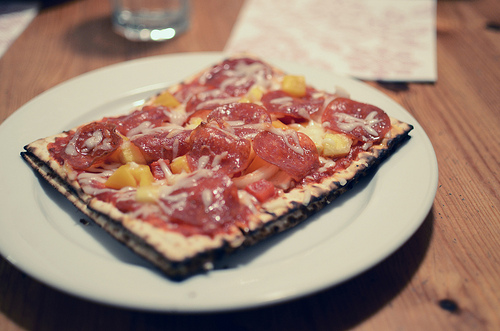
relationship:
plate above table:
[0, 54, 436, 314] [0, 6, 499, 328]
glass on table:
[106, 0, 193, 44] [0, 6, 499, 328]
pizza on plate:
[31, 62, 421, 265] [0, 54, 436, 314]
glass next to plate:
[106, 0, 193, 44] [0, 54, 436, 314]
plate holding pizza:
[0, 54, 436, 314] [115, 87, 343, 201]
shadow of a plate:
[220, 262, 410, 329] [0, 54, 436, 314]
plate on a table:
[0, 54, 436, 314] [437, 15, 484, 308]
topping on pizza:
[185, 120, 253, 175] [31, 62, 421, 265]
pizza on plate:
[31, 62, 421, 265] [10, 40, 432, 296]